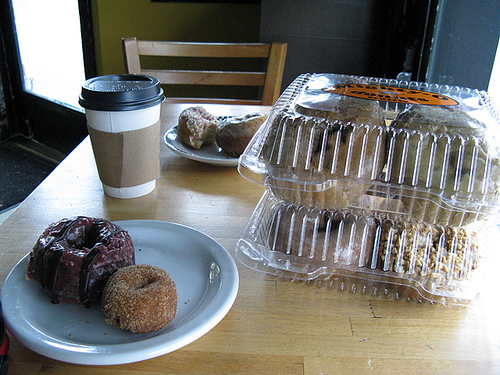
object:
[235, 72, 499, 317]
plastic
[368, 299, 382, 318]
benchmark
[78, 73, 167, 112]
black lid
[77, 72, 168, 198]
coffee cup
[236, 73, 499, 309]
boxes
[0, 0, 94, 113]
window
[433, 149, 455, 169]
ground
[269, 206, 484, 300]
donuts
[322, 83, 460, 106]
sticker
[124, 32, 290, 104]
wood chair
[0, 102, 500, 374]
table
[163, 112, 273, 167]
plate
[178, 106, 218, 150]
donut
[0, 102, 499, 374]
table top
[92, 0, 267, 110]
paint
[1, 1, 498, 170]
wall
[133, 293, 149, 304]
sugar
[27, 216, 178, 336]
donuts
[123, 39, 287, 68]
top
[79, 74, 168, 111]
top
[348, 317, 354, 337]
mark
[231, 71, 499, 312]
package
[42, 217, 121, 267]
sugar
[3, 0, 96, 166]
door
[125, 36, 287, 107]
back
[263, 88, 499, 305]
donuts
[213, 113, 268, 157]
doughtnut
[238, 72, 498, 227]
container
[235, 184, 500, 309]
container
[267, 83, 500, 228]
doughnuts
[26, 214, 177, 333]
treats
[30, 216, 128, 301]
frosting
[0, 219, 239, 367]
plate